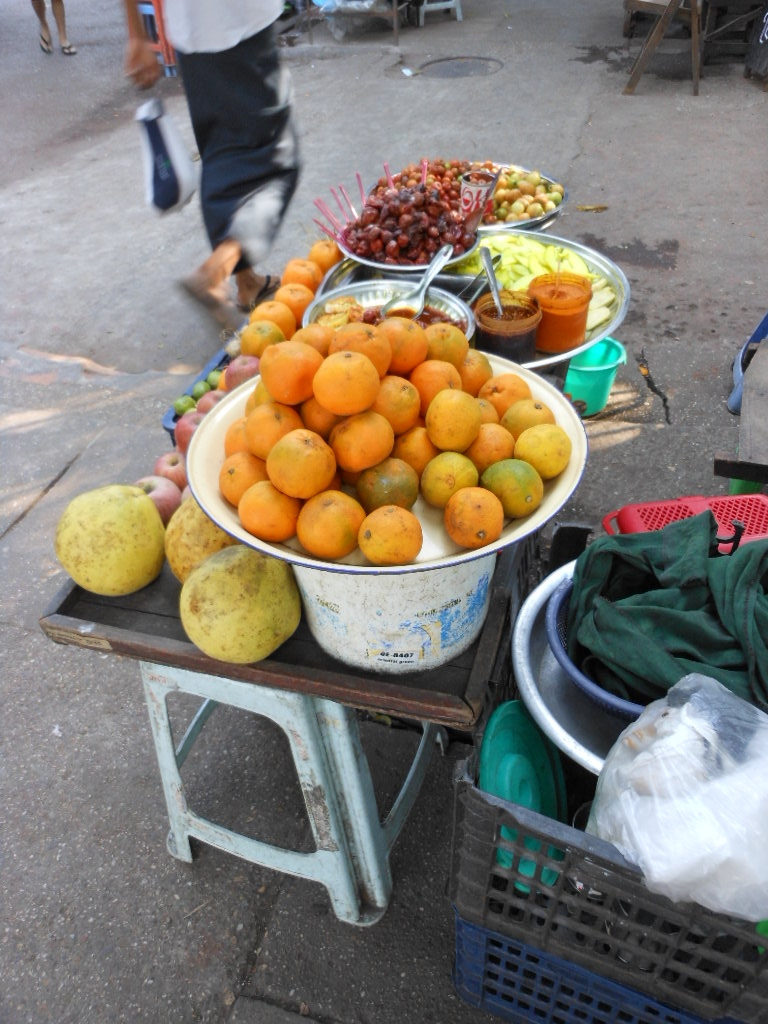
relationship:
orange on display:
[324, 347, 432, 446] [174, 243, 581, 607]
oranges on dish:
[219, 311, 576, 563] [186, 346, 592, 579]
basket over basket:
[447, 520, 768, 1021] [453, 917, 698, 1021]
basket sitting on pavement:
[446, 912, 687, 1022] [4, 3, 766, 1022]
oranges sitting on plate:
[219, 311, 576, 563] [179, 345, 590, 579]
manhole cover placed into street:
[416, 54, 506, 79] [4, 2, 745, 1019]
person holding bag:
[119, 0, 302, 325] [131, 80, 196, 218]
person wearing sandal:
[119, 0, 302, 325] [178, 273, 243, 333]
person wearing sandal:
[119, 0, 302, 325] [231, 272, 279, 311]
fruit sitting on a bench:
[74, 122, 629, 676] [46, 505, 509, 1021]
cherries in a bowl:
[366, 192, 479, 245] [295, 235, 507, 302]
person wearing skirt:
[151, 19, 311, 268] [178, 62, 303, 208]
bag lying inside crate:
[580, 668, 744, 923] [448, 511, 744, 1022]